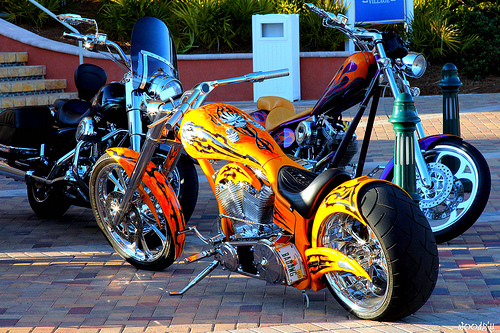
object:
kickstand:
[157, 257, 226, 304]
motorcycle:
[93, 66, 440, 329]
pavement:
[6, 101, 498, 331]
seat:
[275, 154, 340, 224]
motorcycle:
[88, 55, 426, 318]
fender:
[310, 172, 380, 246]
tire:
[324, 181, 436, 326]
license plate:
[277, 246, 313, 296]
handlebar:
[192, 68, 295, 93]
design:
[210, 108, 273, 162]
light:
[142, 74, 185, 112]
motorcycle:
[64, 30, 436, 328]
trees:
[4, 3, 496, 106]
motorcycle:
[102, 48, 440, 320]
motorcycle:
[219, 3, 489, 226]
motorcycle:
[10, 8, 217, 229]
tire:
[302, 181, 443, 321]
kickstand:
[146, 252, 216, 304]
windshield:
[121, 46, 181, 98]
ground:
[1, 88, 495, 328]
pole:
[432, 70, 470, 135]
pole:
[384, 90, 429, 199]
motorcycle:
[253, 6, 498, 253]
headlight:
[399, 55, 426, 82]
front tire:
[84, 148, 187, 275]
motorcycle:
[257, 1, 493, 235]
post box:
[251, 54, 273, 89]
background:
[65, 109, 464, 258]